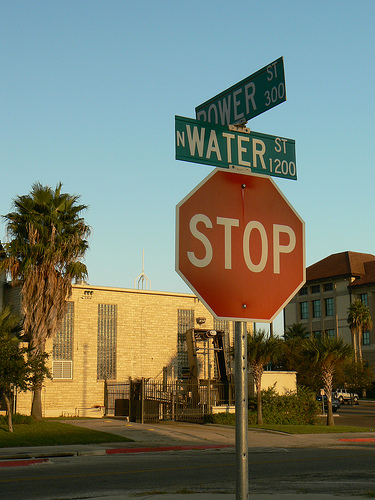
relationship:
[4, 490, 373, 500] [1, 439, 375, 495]
edge of road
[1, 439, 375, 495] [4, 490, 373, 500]
road has an edge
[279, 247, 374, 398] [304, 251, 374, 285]
house has orange roof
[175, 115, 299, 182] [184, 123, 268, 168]
sign says water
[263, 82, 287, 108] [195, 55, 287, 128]
number 300 on sign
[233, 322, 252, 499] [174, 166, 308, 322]
pole under sign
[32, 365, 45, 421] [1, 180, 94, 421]
trunk of a palm tree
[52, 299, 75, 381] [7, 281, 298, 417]
window on building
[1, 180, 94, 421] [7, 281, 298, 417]
palm tree near building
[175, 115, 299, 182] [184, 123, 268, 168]
sign reads water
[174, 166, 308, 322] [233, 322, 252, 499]
sign on a pole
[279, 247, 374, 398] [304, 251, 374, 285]
house ha sa red roof